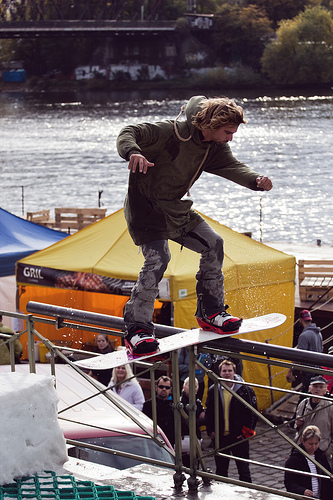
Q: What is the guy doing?
A: Snowboarding.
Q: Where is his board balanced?
A: On a rail.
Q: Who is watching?
A: People from below.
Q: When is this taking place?
A: Daytime.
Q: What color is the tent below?
A: Yellow.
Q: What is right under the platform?
A: A vehicle.